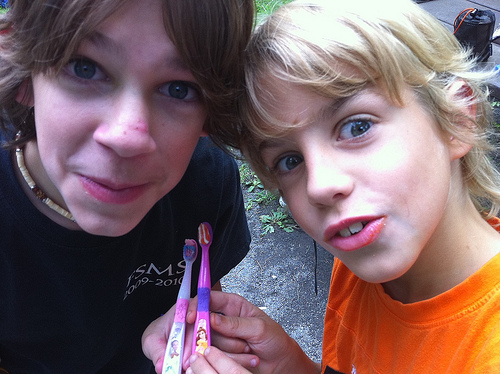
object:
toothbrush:
[193, 215, 220, 360]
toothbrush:
[159, 232, 197, 373]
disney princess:
[190, 323, 214, 359]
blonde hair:
[230, 2, 499, 219]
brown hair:
[4, 0, 260, 173]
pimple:
[128, 116, 150, 139]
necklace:
[6, 127, 78, 225]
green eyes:
[260, 141, 312, 182]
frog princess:
[161, 334, 185, 371]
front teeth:
[336, 217, 371, 241]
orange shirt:
[313, 251, 498, 373]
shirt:
[0, 136, 250, 374]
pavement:
[233, 169, 329, 355]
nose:
[87, 84, 162, 163]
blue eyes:
[56, 46, 123, 93]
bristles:
[194, 217, 215, 251]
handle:
[161, 269, 193, 373]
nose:
[294, 137, 359, 213]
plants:
[233, 159, 301, 250]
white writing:
[116, 252, 196, 307]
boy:
[197, 0, 499, 373]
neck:
[13, 129, 90, 236]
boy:
[1, 3, 262, 371]